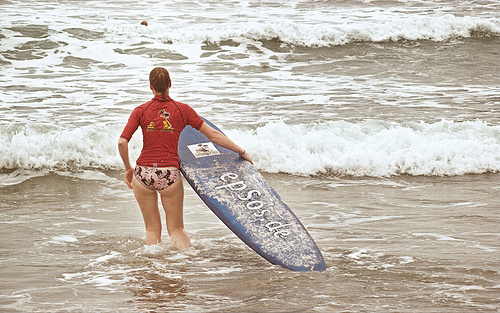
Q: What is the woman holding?
A: Surfboard.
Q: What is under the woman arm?
A: Surfboard.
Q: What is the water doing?
A: Wave rolling.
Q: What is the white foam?
A: Frothy white sea foam.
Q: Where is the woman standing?
A: In the water.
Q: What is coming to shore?
A: Large foam.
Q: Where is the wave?
A: Closer to shore.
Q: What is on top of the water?
A: White foam.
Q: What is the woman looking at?
A: Man in water.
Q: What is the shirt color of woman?
A: Red.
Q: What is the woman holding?
A: A surfboard.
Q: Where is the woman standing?
A: In the water.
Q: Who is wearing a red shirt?
A: The woman.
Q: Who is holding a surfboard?
A: The woman.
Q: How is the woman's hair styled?
A: In a braid.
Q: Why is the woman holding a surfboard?
A: She's going surfing.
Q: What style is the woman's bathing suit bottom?
A: Black and white print.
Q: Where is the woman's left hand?
A: On her hip.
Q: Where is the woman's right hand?
A: On the surfboard.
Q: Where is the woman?
A: At the ocean.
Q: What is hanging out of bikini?
A: Butt cheeks.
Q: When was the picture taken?
A: Daytime.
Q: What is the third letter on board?
A: S.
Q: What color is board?
A: Blue.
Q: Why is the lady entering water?
A: To surf.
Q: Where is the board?
A: In arm.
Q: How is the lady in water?
A: Standing.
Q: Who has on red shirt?
A: The lady.